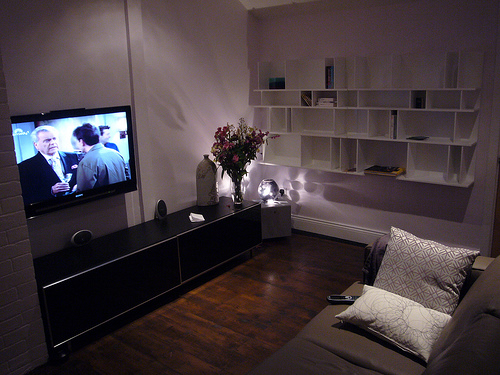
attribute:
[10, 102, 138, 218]
television — turned on, flat screen, on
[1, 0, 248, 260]
wall — white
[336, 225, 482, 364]
pillows — white, decorative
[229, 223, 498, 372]
couch — brown, leather, dark colored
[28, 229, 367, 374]
floor — brown, parquet, rich brown, hardwood, wood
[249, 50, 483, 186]
shelves — white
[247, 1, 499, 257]
wall — white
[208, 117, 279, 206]
flowers — multicolor, multi-color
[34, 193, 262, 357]
stand — wood, long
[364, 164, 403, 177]
book — large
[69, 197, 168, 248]
speakers — round, surround sound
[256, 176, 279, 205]
vase — round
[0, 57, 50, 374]
wall — brown, brick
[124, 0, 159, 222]
trim — beveled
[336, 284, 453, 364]
pillow — square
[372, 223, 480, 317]
pillow — square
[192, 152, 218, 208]
pottery vase — tall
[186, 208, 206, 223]
book — white, small